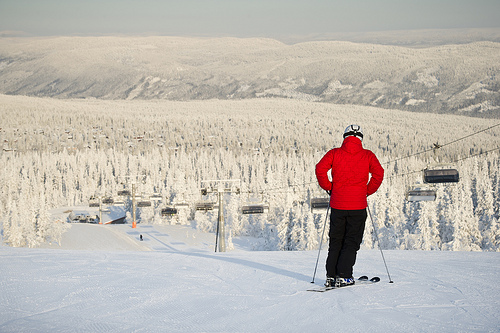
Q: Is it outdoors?
A: Yes, it is outdoors.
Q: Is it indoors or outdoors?
A: It is outdoors.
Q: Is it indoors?
A: No, it is outdoors.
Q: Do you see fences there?
A: No, there are no fences.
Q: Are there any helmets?
A: Yes, there is a helmet.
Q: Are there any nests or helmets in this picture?
A: Yes, there is a helmet.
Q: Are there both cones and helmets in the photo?
A: Yes, there are both a helmet and a cone.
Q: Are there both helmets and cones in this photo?
A: Yes, there are both a helmet and a cone.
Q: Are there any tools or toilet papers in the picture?
A: No, there are no tools or toilet papers.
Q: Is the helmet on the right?
A: Yes, the helmet is on the right of the image.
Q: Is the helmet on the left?
A: No, the helmet is on the right of the image.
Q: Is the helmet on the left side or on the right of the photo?
A: The helmet is on the right of the image.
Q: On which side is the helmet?
A: The helmet is on the right of the image.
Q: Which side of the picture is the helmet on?
A: The helmet is on the right of the image.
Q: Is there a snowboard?
A: No, there are no snowboards.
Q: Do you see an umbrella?
A: No, there are no umbrellas.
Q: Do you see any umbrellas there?
A: No, there are no umbrellas.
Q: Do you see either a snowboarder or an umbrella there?
A: No, there are no umbrellas or snowboarders.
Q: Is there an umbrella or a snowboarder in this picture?
A: No, there are no umbrellas or snowboarders.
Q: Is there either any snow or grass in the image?
A: Yes, there is snow.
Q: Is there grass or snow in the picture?
A: Yes, there is snow.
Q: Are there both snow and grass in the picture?
A: No, there is snow but no grass.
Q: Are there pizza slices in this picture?
A: No, there are no pizza slices.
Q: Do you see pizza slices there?
A: No, there are no pizza slices.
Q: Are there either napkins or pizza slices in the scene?
A: No, there are no pizza slices or napkins.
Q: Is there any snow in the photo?
A: Yes, there is snow.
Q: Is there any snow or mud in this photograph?
A: Yes, there is snow.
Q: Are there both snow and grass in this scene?
A: No, there is snow but no grass.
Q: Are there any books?
A: No, there are no books.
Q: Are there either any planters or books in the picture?
A: No, there are no books or planters.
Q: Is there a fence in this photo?
A: No, there are no fences.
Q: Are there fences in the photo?
A: No, there are no fences.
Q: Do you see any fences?
A: No, there are no fences.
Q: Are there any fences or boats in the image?
A: No, there are no fences or boats.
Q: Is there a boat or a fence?
A: No, there are no fences or boats.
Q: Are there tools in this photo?
A: No, there are no tools.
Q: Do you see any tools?
A: No, there are no tools.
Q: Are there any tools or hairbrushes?
A: No, there are no tools or hairbrushes.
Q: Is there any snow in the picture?
A: Yes, there is snow.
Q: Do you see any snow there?
A: Yes, there is snow.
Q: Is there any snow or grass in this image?
A: Yes, there is snow.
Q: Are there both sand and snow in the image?
A: No, there is snow but no sand.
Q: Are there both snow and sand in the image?
A: No, there is snow but no sand.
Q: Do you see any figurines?
A: No, there are no figurines.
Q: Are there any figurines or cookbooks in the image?
A: No, there are no figurines or cookbooks.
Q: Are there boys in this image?
A: No, there are no boys.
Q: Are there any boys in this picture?
A: No, there are no boys.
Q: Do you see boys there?
A: No, there are no boys.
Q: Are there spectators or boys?
A: No, there are no boys or spectators.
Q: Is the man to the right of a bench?
A: No, the man is to the left of a bench.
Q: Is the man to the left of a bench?
A: Yes, the man is to the left of a bench.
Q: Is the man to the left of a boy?
A: No, the man is to the left of a bench.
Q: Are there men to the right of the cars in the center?
A: Yes, there is a man to the right of the cars.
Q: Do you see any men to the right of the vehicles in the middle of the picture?
A: Yes, there is a man to the right of the cars.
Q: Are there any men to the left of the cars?
A: No, the man is to the right of the cars.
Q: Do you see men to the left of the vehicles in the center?
A: No, the man is to the right of the cars.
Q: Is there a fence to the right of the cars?
A: No, there is a man to the right of the cars.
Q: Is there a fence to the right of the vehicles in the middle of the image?
A: No, there is a man to the right of the cars.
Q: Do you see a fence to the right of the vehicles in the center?
A: No, there is a man to the right of the cars.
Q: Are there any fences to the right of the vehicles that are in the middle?
A: No, there is a man to the right of the cars.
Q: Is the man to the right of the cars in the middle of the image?
A: Yes, the man is to the right of the cars.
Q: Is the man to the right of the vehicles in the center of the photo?
A: Yes, the man is to the right of the cars.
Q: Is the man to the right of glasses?
A: No, the man is to the right of the cars.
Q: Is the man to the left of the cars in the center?
A: No, the man is to the right of the cars.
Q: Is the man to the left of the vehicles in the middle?
A: No, the man is to the right of the cars.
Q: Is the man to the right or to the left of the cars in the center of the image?
A: The man is to the right of the cars.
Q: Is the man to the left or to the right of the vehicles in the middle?
A: The man is to the right of the cars.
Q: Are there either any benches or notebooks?
A: Yes, there is a bench.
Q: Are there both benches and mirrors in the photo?
A: No, there is a bench but no mirrors.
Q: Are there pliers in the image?
A: No, there are no pliers.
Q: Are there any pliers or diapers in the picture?
A: No, there are no pliers or diapers.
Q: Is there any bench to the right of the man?
A: Yes, there is a bench to the right of the man.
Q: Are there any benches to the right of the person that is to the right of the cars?
A: Yes, there is a bench to the right of the man.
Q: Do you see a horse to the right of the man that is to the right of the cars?
A: No, there is a bench to the right of the man.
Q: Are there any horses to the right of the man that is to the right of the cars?
A: No, there is a bench to the right of the man.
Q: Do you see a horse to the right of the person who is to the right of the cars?
A: No, there is a bench to the right of the man.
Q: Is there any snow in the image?
A: Yes, there is snow.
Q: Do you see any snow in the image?
A: Yes, there is snow.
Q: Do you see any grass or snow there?
A: Yes, there is snow.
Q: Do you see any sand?
A: No, there is no sand.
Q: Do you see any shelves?
A: No, there are no shelves.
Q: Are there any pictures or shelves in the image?
A: No, there are no shelves or pictures.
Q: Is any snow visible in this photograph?
A: Yes, there is snow.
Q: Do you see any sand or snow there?
A: Yes, there is snow.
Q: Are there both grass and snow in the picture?
A: No, there is snow but no grass.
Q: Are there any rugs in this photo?
A: No, there are no rugs.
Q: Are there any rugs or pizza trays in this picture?
A: No, there are no rugs or pizza trays.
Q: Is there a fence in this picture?
A: No, there are no fences.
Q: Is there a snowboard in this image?
A: No, there are no snowboards.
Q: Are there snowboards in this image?
A: No, there are no snowboards.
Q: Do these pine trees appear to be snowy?
A: Yes, the pine trees are snowy.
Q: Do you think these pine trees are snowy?
A: Yes, the pine trees are snowy.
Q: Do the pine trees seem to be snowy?
A: Yes, the pine trees are snowy.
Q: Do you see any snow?
A: Yes, there is snow.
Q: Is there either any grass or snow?
A: Yes, there is snow.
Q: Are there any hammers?
A: No, there are no hammers.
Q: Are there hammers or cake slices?
A: No, there are no hammers or cake slices.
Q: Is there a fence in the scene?
A: No, there are no fences.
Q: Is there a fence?
A: No, there are no fences.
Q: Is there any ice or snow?
A: Yes, there is snow.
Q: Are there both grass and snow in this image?
A: No, there is snow but no grass.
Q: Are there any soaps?
A: No, there are no soaps.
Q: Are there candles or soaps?
A: No, there are no soaps or candles.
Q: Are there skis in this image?
A: Yes, there are skis.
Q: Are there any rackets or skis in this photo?
A: Yes, there are skis.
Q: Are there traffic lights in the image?
A: No, there are no traffic lights.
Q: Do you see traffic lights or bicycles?
A: No, there are no traffic lights or bicycles.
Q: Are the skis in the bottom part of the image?
A: Yes, the skis are in the bottom of the image.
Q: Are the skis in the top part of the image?
A: No, the skis are in the bottom of the image.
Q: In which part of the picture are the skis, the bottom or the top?
A: The skis are in the bottom of the image.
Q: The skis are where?
A: The skis are in the snow.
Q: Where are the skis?
A: The skis are in the snow.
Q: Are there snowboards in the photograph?
A: No, there are no snowboards.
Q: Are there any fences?
A: No, there are no fences.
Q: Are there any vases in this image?
A: No, there are no vases.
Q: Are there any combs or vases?
A: No, there are no vases or combs.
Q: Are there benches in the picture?
A: Yes, there is a bench.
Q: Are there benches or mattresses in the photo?
A: Yes, there is a bench.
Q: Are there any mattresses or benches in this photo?
A: Yes, there is a bench.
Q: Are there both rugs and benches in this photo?
A: No, there is a bench but no rugs.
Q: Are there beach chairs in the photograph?
A: No, there are no beach chairs.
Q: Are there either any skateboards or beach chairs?
A: No, there are no beach chairs or skateboards.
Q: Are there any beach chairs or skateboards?
A: No, there are no beach chairs or skateboards.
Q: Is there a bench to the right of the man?
A: Yes, there is a bench to the right of the man.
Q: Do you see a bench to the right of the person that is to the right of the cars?
A: Yes, there is a bench to the right of the man.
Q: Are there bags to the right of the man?
A: No, there is a bench to the right of the man.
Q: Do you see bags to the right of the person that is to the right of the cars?
A: No, there is a bench to the right of the man.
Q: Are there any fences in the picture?
A: No, there are no fences.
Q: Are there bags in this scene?
A: No, there are no bags.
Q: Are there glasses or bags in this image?
A: No, there are no bags or glasses.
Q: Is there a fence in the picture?
A: No, there are no fences.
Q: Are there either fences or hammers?
A: No, there are no fences or hammers.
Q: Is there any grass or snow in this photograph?
A: Yes, there is snow.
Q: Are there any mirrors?
A: No, there are no mirrors.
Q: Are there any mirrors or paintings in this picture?
A: No, there are no mirrors or paintings.